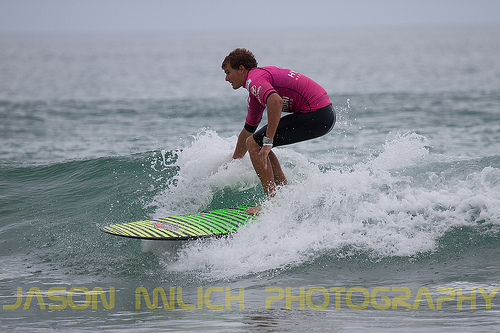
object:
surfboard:
[100, 203, 262, 241]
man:
[220, 48, 337, 215]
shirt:
[243, 65, 333, 134]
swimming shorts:
[252, 103, 336, 149]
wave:
[128, 99, 499, 280]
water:
[2, 28, 498, 333]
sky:
[1, 0, 500, 26]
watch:
[262, 136, 273, 144]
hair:
[222, 47, 259, 70]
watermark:
[0, 286, 500, 309]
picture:
[1, 1, 500, 332]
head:
[221, 48, 257, 89]